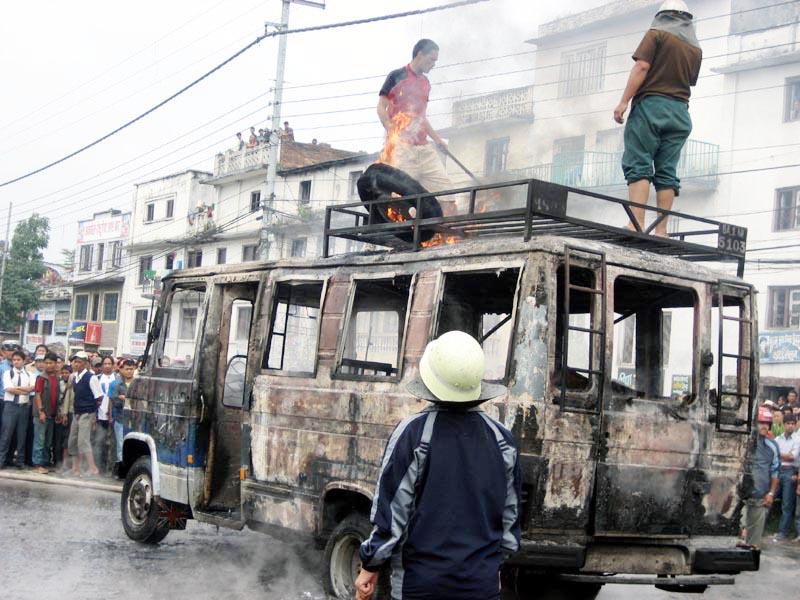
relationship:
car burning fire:
[118, 234, 762, 600] [365, 105, 499, 254]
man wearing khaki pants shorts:
[377, 38, 456, 241] [386, 145, 464, 205]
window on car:
[610, 280, 694, 403] [118, 202, 763, 597]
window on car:
[556, 268, 594, 396] [118, 202, 763, 597]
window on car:
[340, 276, 406, 370] [118, 202, 763, 597]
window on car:
[168, 285, 201, 365] [118, 202, 763, 597]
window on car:
[610, 273, 697, 404] [118, 202, 763, 597]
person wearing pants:
[62, 346, 100, 464] [67, 417, 95, 475]